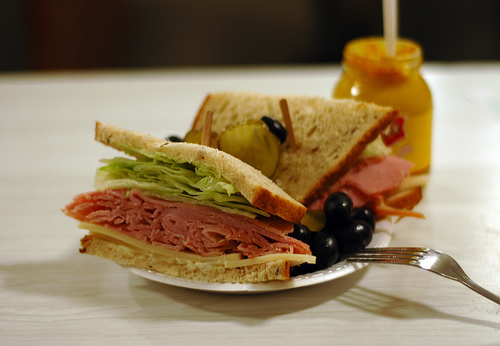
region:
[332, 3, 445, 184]
an open bottle of mustard beside the dish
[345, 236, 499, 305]
a fork is upside down on the plate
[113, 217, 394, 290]
the plate is white under the fork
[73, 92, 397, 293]
wheat bread is on the sandwich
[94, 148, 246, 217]
green lettuce is on the sandwich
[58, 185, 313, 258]
thin sliced ham is under the lettuce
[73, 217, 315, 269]
slices of cheese are under the ham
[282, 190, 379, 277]
a pile of black olives is on the plate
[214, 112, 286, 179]
a sliced pickle is on top of the sandwich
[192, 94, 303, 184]
toothpicks are in the sandwich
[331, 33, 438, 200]
Bottle of mustard with a utensil in it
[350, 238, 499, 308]
Fork leaning on the side of the plate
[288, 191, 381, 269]
Small pile of olives on the edge of the plate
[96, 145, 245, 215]
Stack of green lettuce under the bread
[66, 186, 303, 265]
Mound of sliced meat in the middle of the sandwich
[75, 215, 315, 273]
Slices of white cheese under the meat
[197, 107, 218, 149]
toothpick holding the sandwich together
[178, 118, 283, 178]
Two dill pickle slices on top of the sandwich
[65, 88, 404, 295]
Sandwich sitting on a styrofoam plate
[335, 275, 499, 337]
Shadow of a fork on the table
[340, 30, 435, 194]
open jar of mustard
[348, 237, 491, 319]
fork resting on white plate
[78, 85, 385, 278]
sandwich on white plate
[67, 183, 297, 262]
ham on the sandwich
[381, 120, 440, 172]
red and yellow label on mustard jar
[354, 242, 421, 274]
tines of the fork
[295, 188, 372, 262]
black olives on white plate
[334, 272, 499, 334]
shadow of fork on table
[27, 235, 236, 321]
shadow of plate and sandwich on table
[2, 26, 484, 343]
white tablecloth on table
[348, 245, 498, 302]
Tine portion of a metal fork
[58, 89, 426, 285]
Sandwich cut in half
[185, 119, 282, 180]
Slices of pickles on a sandwich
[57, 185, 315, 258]
Slices of meat on a sandwich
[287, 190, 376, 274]
Several olives on a plate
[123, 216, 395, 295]
Small white plastic disposable plate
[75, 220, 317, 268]
Slices white cheese on a sandwich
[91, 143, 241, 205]
Shredded lettuce on a sandwich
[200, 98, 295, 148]
Two sticks each in half a sandwich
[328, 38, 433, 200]
A jar filled with some sort of liquid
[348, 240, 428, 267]
several shiny metal fork tines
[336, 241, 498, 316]
one metal fork perched on plate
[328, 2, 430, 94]
one plastic utensil handle stuck in jar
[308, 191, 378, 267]
several shiny dark olives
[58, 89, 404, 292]
one cut up sandwich on plate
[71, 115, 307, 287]
half of meat and cheese sandwich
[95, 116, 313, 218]
top slice of sandwich bread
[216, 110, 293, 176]
one green pickle slice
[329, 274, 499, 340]
shadow of fork tines on table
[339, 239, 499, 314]
fork propped on small plate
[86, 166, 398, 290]
plate holding sandwich halves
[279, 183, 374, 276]
olives stacked on plate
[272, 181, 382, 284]
olives on plate are black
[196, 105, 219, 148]
toothpick on sandwich half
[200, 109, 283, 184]
sliced pickle between sandwich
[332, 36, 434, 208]
jar on table by plate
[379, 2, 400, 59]
utensil inside small jar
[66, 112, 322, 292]
sandwich half on plate